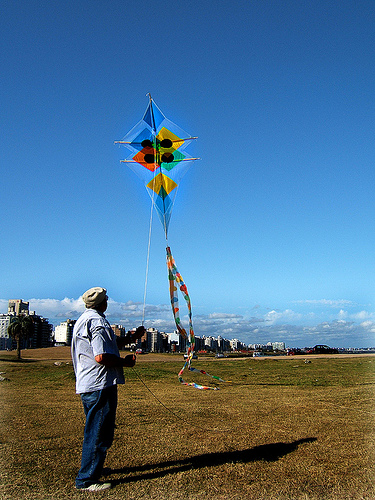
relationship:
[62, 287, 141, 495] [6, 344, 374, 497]
man on grass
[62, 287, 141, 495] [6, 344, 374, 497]
man standing on grass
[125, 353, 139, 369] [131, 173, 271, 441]
hand holding string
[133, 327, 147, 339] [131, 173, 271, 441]
hand holding string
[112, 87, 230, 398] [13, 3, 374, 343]
kite in sky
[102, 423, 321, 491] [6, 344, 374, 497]
shadow on grass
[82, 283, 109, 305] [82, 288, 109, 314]
cap on head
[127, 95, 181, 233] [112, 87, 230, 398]
design on kite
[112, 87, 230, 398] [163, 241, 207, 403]
kite has tail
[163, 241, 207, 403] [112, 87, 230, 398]
tail on kite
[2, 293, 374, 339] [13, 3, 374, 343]
clouds low in sky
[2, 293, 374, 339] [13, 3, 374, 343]
clouds in sky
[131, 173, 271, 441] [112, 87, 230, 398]
string attached to kite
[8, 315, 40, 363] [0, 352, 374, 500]
palm tree in grass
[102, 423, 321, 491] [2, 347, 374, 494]
shadow on ground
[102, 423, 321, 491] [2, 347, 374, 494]
shadow cast on ground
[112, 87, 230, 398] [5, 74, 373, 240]
kite in mid air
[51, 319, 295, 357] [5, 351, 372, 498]
buildings line landscape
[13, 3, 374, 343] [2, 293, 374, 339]
sky with clouds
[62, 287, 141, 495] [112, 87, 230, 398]
man flying kite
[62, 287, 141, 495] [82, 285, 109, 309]
man wearing cap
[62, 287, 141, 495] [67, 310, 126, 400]
man wearing shirt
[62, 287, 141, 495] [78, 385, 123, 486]
man wearing jeans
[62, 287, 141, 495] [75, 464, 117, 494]
man wearing sneakers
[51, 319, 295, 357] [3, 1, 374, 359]
buildings in background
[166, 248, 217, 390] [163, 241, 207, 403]
dots on tail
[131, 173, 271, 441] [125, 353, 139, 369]
string in hand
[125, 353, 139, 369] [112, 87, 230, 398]
hand flying kite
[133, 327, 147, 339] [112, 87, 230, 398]
hand flying kite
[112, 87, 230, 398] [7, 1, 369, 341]
kite in air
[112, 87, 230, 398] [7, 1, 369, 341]
kite flying in air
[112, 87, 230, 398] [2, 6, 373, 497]
kite in wind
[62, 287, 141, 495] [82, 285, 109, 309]
man in cap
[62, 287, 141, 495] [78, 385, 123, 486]
man in jeans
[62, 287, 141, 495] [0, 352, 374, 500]
man standing in grass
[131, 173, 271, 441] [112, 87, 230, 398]
twine attached to kite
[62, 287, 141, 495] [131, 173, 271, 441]
man holding twine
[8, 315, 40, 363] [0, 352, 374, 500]
palm tree on grass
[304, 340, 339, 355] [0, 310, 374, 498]
car next to park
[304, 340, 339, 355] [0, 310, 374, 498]
car parked next to park